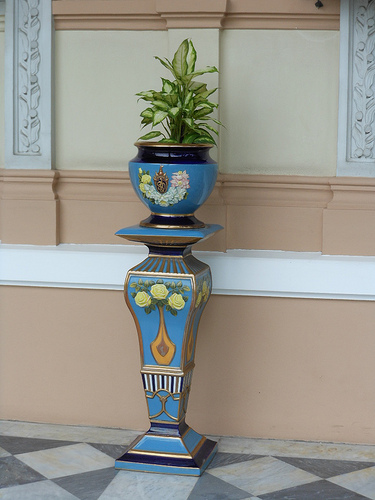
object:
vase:
[128, 139, 220, 229]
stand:
[114, 225, 222, 479]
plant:
[135, 36, 228, 147]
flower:
[130, 279, 189, 366]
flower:
[137, 165, 190, 206]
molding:
[238, 173, 259, 206]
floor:
[0, 417, 372, 500]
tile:
[209, 454, 320, 498]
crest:
[134, 142, 214, 149]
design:
[15, 0, 42, 154]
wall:
[0, 0, 375, 453]